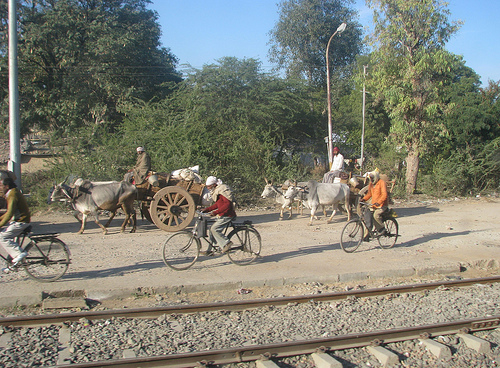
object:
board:
[59, 326, 71, 366]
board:
[122, 349, 136, 357]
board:
[456, 293, 477, 304]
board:
[1, 326, 12, 348]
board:
[461, 333, 491, 354]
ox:
[283, 176, 350, 227]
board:
[311, 353, 343, 367]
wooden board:
[364, 345, 399, 364]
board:
[417, 338, 452, 359]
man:
[0, 174, 32, 263]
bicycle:
[0, 225, 72, 283]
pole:
[7, 0, 22, 192]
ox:
[51, 175, 139, 235]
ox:
[69, 177, 118, 186]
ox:
[260, 177, 301, 220]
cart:
[134, 171, 206, 232]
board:
[122, 349, 136, 359]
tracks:
[1, 275, 500, 368]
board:
[170, 320, 184, 331]